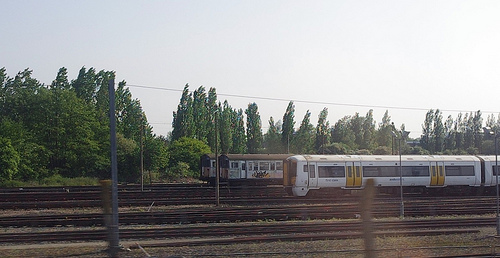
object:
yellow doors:
[428, 159, 447, 189]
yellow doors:
[341, 157, 363, 189]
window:
[355, 163, 433, 178]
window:
[225, 159, 240, 168]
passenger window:
[443, 164, 465, 176]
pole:
[100, 73, 124, 247]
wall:
[228, 152, 272, 174]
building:
[197, 147, 293, 180]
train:
[285, 152, 497, 193]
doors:
[344, 162, 362, 190]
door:
[430, 158, 444, 190]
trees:
[0, 75, 38, 190]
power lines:
[94, 78, 340, 106]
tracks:
[19, 213, 500, 239]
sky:
[382, 76, 406, 101]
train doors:
[344, 161, 361, 185]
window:
[324, 168, 346, 178]